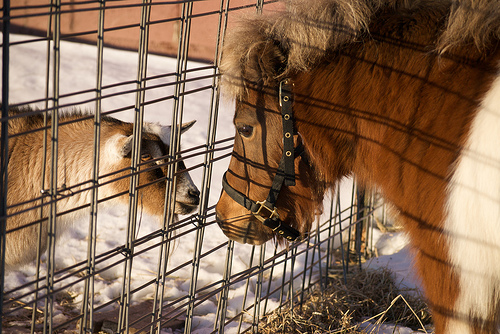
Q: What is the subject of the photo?
A: Animals.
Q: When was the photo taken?
A: Winter.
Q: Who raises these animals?
A: Farmer.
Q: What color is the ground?
A: White.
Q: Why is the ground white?
A: Snow.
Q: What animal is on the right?
A: Horse.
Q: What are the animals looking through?
A: Wire fence.